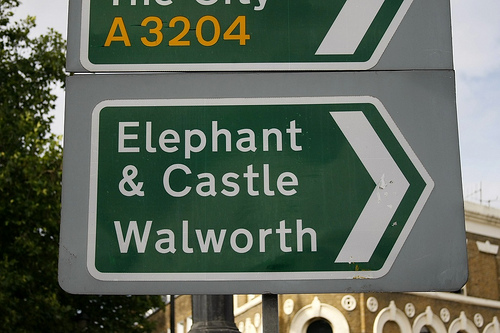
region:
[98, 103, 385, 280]
the sign is green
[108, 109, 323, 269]
the letters are white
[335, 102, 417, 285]
the arrow is white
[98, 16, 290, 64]
the letters are in yellow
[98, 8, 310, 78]
the letters say A3204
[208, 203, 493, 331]
the building is brown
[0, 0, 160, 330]
the tree is green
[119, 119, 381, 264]
the sign says elephant & castle walworth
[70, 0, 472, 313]
the sign is gray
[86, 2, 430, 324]
2 green signs are on the bigger sign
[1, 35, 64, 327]
Trees are in the background.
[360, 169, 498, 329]
A building is behind the sign.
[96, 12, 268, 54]
The letters and numbers are in yellow.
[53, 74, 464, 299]
The sign has a grey background.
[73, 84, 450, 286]
The sign is in English.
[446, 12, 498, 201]
The sky is overcast.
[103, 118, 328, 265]
The letters are in white.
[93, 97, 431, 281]
The background is green.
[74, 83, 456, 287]
A traffic sign.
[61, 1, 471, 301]
Two signs are shown.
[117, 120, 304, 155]
the word Elephant on a sign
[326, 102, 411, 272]
a white arrow on a green sign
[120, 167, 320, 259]
the words Castle Walworth on a sign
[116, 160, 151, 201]
the & symbol on a green sign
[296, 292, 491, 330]
a series of arches on a brown building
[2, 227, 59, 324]
a green tree in the background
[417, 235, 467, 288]
the grey corner of a sign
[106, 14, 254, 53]
the number A3204 in yellow on a sign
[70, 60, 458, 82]
the dividing line between two signs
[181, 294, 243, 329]
the metal pole below two signs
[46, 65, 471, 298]
The sign is white, green, and gray.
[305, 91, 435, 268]
The sign has an arrow on it.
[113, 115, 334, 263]
The text on the sign says Elephant & Castle Walworth.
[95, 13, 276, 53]
The text on the sign is yellow.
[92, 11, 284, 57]
The text on the sign says A 3204.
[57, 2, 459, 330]
The signs are attached to a pole.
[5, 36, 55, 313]
A green tree is in the background.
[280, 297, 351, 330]
A white arch is on the building.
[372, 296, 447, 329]
Two white arches are next to each other.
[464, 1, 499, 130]
The sky is slightly cloudy.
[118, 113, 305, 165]
The english word elephant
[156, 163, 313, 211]
The word "castle" with C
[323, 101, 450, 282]
An arrow pointing right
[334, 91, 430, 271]
A white and green arrow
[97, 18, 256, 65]
A district number code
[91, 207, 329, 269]
The english word "Walworth"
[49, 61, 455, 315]
A sign indicating a location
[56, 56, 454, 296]
A metallic street sign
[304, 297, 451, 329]
The facade of a building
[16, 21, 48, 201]
Branches of a tall tree